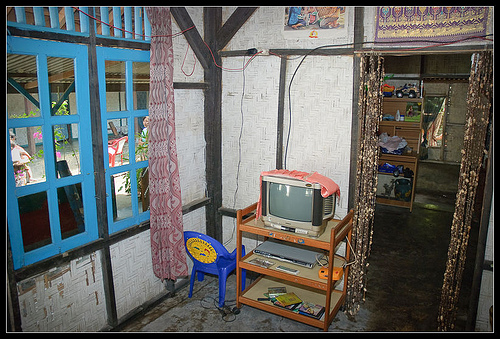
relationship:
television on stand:
[261, 174, 335, 238] [241, 224, 345, 328]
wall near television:
[256, 54, 347, 153] [261, 174, 335, 238]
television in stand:
[261, 174, 335, 238] [241, 224, 345, 328]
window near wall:
[12, 36, 162, 250] [256, 54, 347, 153]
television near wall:
[261, 174, 335, 238] [256, 54, 347, 153]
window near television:
[12, 36, 162, 250] [261, 174, 335, 238]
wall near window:
[256, 54, 347, 153] [12, 36, 162, 250]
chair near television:
[166, 232, 226, 305] [261, 174, 335, 238]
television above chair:
[261, 174, 335, 238] [166, 232, 226, 305]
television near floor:
[261, 174, 335, 238] [166, 287, 220, 329]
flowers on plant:
[32, 130, 61, 159] [13, 96, 69, 176]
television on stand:
[259, 169, 338, 237] [232, 200, 352, 328]